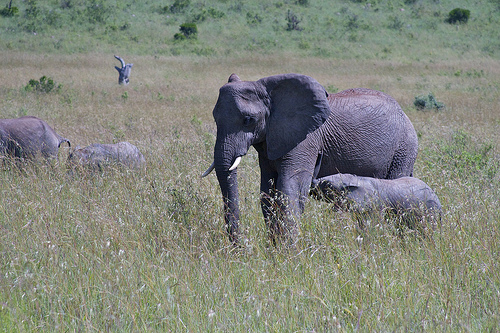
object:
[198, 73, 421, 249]
elephant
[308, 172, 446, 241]
elephant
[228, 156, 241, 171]
tusks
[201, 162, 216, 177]
tusks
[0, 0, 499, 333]
grass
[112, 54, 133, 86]
tree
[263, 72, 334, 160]
ear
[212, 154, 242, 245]
trunk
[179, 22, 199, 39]
bushes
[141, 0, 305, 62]
hill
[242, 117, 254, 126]
eye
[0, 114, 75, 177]
elephants